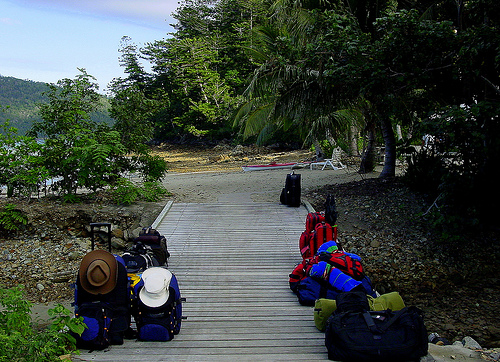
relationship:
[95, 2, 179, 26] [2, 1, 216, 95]
clouds in sky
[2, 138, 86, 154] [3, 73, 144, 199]
water behind trees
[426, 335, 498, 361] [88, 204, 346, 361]
rocks by bridge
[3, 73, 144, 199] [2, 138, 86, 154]
trees near water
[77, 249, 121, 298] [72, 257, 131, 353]
hat on backpack